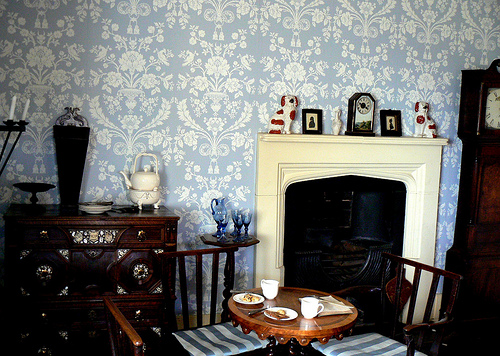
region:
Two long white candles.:
[7, 95, 34, 121]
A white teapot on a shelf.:
[116, 150, 164, 210]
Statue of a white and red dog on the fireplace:
[267, 90, 299, 135]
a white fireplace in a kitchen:
[252, 131, 448, 326]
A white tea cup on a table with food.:
[300, 295, 325, 320]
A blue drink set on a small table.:
[206, 195, 252, 242]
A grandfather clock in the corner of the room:
[434, 55, 491, 354]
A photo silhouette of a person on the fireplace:
[300, 105, 321, 130]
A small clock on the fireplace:
[345, 92, 378, 134]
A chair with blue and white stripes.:
[317, 258, 465, 355]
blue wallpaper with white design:
[0, 2, 496, 312]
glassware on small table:
[199, 195, 259, 316]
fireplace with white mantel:
[255, 134, 449, 295]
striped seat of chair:
[316, 332, 421, 354]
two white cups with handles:
[259, 278, 324, 319]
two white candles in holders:
[6, 96, 31, 127]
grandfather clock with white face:
[448, 62, 498, 349]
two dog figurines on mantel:
[268, 93, 442, 136]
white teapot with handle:
[121, 153, 163, 208]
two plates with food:
[236, 292, 297, 323]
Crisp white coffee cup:
[261, 278, 281, 299]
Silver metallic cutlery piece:
[246, 308, 260, 318]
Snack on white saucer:
[261, 302, 297, 321]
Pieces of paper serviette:
[326, 291, 352, 319]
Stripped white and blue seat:
[351, 333, 401, 354]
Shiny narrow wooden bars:
[379, 245, 458, 323]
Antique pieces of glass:
[206, 190, 256, 238]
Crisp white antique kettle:
[117, 148, 166, 209]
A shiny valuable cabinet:
[8, 213, 175, 293]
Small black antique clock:
[346, 88, 376, 134]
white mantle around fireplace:
[253, 134, 449, 324]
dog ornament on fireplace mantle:
[266, 92, 301, 134]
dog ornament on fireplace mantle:
[413, 99, 437, 139]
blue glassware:
[208, 197, 253, 243]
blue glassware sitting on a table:
[200, 196, 261, 321]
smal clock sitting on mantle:
[343, 90, 375, 139]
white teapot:
[118, 153, 165, 210]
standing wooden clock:
[443, 57, 499, 354]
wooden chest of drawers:
[0, 202, 179, 354]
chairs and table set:
[99, 254, 466, 355]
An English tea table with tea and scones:
[221, 271, 369, 355]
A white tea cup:
[258, 274, 281, 297]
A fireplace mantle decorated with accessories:
[261, 83, 451, 157]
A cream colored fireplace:
[254, 132, 444, 316]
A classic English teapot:
[117, 150, 171, 211]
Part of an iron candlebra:
[3, 87, 33, 165]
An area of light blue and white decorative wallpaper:
[91, 5, 453, 90]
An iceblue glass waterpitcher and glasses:
[203, 191, 254, 239]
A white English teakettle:
[116, 145, 175, 218]